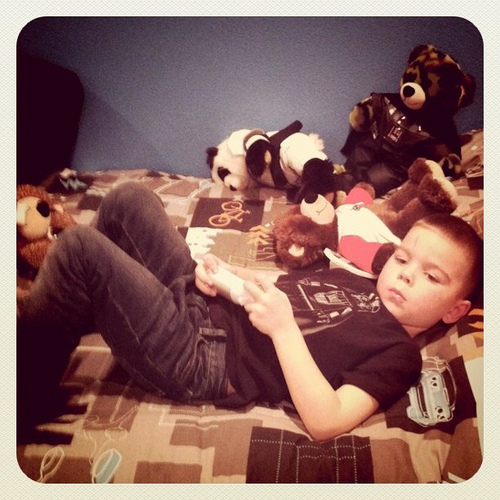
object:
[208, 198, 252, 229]
bicycle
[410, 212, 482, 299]
brown hair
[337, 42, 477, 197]
bear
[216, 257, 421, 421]
tshirt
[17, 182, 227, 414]
pant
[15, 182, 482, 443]
boy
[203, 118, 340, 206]
bear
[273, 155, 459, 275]
bear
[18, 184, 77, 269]
bear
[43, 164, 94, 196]
football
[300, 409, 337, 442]
elbow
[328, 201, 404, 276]
shirt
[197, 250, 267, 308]
remote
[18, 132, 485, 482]
bedspread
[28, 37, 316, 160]
blue wall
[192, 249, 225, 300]
hand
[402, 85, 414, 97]
nose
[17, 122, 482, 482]
bed